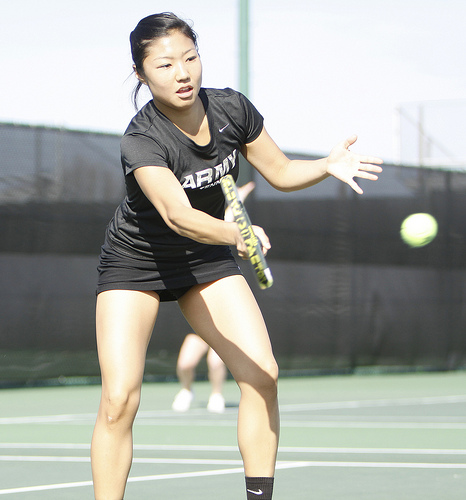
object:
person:
[93, 13, 384, 499]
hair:
[122, 11, 200, 113]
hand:
[236, 223, 272, 263]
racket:
[219, 173, 275, 291]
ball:
[399, 211, 439, 251]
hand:
[325, 135, 382, 196]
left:
[383, 0, 466, 497]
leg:
[90, 274, 162, 500]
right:
[1, 0, 95, 500]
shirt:
[105, 86, 265, 262]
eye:
[156, 63, 172, 69]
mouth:
[175, 84, 194, 99]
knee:
[251, 359, 280, 391]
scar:
[108, 415, 113, 422]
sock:
[244, 476, 274, 499]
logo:
[246, 488, 263, 495]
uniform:
[96, 86, 265, 299]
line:
[0, 454, 466, 469]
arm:
[119, 131, 274, 263]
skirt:
[96, 214, 244, 295]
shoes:
[171, 387, 193, 412]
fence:
[0, 123, 466, 392]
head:
[129, 12, 203, 110]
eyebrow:
[182, 48, 194, 56]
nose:
[175, 57, 191, 83]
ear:
[132, 62, 148, 87]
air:
[1, 7, 465, 499]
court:
[0, 352, 465, 499]